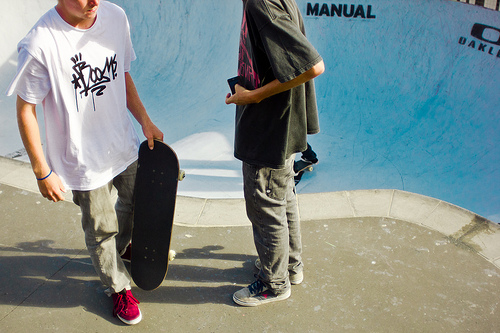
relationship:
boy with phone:
[222, 5, 331, 264] [212, 66, 269, 124]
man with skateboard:
[15, 2, 190, 332] [130, 143, 187, 310]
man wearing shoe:
[15, 2, 190, 332] [96, 278, 152, 333]